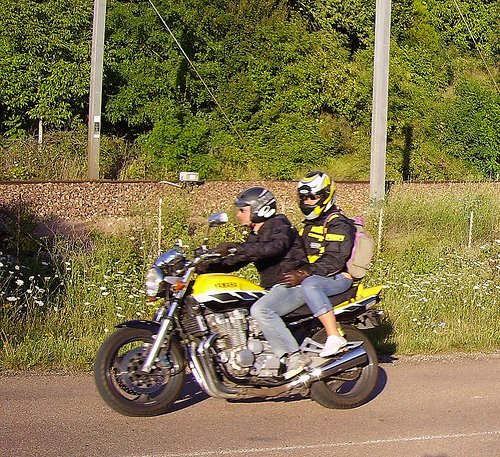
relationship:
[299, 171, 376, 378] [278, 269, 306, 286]
woman wearing leather gloves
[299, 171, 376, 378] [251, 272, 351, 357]
woman wearing blue jeans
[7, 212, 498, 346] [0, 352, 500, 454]
flowers growing next to highway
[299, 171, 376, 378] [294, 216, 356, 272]
woman in jacket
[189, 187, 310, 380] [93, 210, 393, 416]
man on motorcycle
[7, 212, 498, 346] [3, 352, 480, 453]
flowers growing along road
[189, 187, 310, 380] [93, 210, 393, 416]
man riding motorcycle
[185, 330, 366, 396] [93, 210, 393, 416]
muffler of motorcycle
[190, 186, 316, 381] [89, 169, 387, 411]
person on motorcycle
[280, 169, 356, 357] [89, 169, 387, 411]
person on motorcycle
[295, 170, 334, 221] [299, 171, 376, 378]
helmet of woman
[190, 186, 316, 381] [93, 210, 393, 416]
person on motorcycle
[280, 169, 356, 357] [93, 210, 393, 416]
person on motorcycle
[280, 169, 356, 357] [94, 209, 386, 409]
person on bike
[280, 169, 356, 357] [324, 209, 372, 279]
person has backpack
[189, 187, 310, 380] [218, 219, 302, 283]
man has black jacket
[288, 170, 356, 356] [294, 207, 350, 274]
lady has jacket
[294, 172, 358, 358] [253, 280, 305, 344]
passenger wearing blue jeans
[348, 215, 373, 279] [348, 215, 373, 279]
brown backpack with brown backpack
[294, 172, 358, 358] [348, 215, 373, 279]
passenger with brown backpack